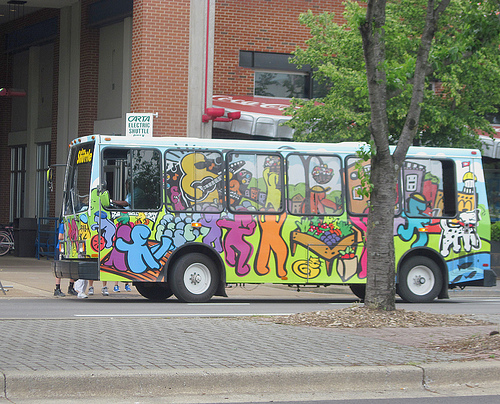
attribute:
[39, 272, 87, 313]
shoes — black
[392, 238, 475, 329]
wheel — black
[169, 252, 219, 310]
wheel — round, front wheel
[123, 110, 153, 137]
sign — white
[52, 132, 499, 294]
bus — passenger bus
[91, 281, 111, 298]
shoe — white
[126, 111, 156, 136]
writing — green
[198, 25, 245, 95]
building — red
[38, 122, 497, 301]
bus — decorated, multicolored